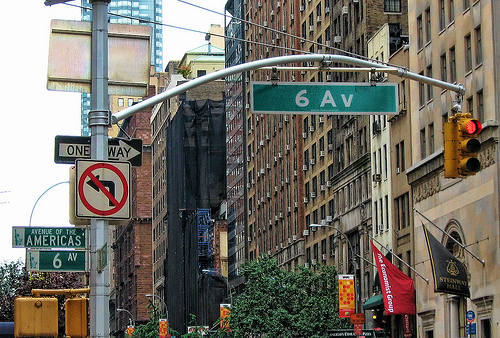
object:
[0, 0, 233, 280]
sky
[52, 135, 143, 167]
black sign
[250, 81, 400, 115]
sign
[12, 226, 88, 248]
sign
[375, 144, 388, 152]
ground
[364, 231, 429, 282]
pole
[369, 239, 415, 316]
flag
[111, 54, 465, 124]
pole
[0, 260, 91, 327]
trees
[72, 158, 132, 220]
sign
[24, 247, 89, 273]
sign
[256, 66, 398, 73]
pole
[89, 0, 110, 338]
pole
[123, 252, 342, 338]
tree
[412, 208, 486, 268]
flag pole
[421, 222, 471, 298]
flag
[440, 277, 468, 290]
lettering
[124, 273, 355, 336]
banners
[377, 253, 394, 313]
white lettering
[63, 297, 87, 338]
light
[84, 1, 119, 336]
pole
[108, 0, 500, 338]
buildings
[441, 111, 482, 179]
light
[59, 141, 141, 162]
arrow